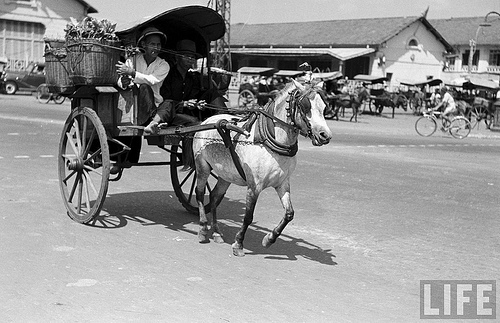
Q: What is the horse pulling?
A: A wagon.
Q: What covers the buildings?
A: Roofs.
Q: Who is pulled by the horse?
A: A man.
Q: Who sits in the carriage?
A: Two men.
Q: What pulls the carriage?
A: A horse.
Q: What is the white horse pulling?
A: A carriage.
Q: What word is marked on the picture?
A: LIFE.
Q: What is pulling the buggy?
A: Horse.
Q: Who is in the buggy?
A: Two men.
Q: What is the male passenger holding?
A: A barrel.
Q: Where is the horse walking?
A: On the road.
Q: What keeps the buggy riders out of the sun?
A: An awning on the buggy.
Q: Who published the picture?
A: LIFE.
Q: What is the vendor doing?
A: Transporting goods.